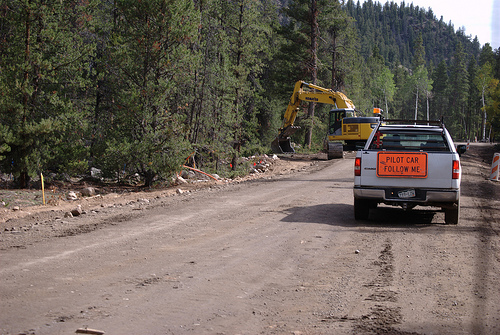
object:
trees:
[0, 7, 500, 186]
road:
[0, 159, 500, 333]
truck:
[353, 119, 463, 225]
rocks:
[45, 149, 219, 221]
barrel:
[489, 152, 499, 182]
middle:
[326, 141, 344, 160]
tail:
[353, 154, 363, 178]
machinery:
[270, 80, 386, 160]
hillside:
[0, 0, 497, 190]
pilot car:
[376, 150, 428, 178]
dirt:
[217, 153, 279, 174]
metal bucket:
[270, 136, 296, 154]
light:
[354, 157, 361, 176]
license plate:
[396, 189, 416, 199]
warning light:
[372, 106, 382, 116]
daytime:
[0, 0, 497, 335]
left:
[0, 145, 295, 196]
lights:
[451, 160, 459, 179]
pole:
[41, 173, 46, 207]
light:
[373, 108, 380, 114]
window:
[366, 129, 453, 151]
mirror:
[457, 144, 468, 155]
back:
[352, 150, 460, 225]